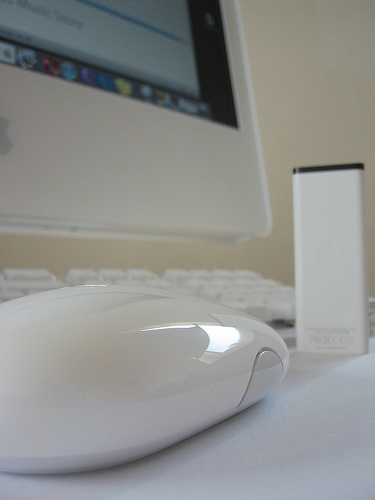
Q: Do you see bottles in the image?
A: No, there are no bottles.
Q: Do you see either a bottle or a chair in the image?
A: No, there are no bottles or chairs.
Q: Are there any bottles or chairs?
A: No, there are no bottles or chairs.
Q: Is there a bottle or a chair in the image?
A: No, there are no bottles or chairs.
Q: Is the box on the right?
A: Yes, the box is on the right of the image.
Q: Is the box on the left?
A: No, the box is on the right of the image.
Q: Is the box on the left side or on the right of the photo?
A: The box is on the right of the image.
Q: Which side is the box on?
A: The box is on the right of the image.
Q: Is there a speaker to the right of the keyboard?
A: No, there is a box to the right of the keyboard.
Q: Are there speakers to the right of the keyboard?
A: No, there is a box to the right of the keyboard.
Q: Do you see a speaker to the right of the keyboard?
A: No, there is a box to the right of the keyboard.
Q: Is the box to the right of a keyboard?
A: Yes, the box is to the right of a keyboard.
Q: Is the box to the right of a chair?
A: No, the box is to the right of a keyboard.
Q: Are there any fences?
A: No, there are no fences.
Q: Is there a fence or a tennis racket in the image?
A: No, there are no fences or rackets.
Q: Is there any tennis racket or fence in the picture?
A: No, there are no fences or rackets.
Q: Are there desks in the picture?
A: Yes, there is a desk.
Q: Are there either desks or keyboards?
A: Yes, there is a desk.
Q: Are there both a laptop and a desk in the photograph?
A: No, there is a desk but no laptops.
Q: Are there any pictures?
A: No, there are no pictures.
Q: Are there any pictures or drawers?
A: No, there are no pictures or drawers.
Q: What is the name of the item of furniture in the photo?
A: The piece of furniture is a desk.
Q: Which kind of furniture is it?
A: The piece of furniture is a desk.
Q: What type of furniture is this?
A: This is a desk.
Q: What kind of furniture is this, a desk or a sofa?
A: This is a desk.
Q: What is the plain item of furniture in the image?
A: The piece of furniture is a desk.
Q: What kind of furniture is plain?
A: The furniture is a desk.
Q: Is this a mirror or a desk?
A: This is a desk.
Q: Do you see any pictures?
A: No, there are no pictures.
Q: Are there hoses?
A: No, there are no hoses.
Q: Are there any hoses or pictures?
A: No, there are no hoses or pictures.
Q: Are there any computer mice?
A: Yes, there is a computer mouse.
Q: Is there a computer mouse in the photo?
A: Yes, there is a computer mouse.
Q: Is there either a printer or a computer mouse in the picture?
A: Yes, there is a computer mouse.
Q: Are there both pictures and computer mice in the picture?
A: No, there is a computer mouse but no pictures.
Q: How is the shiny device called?
A: The device is a computer mouse.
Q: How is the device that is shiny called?
A: The device is a computer mouse.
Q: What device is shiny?
A: The device is a computer mouse.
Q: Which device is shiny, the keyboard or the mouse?
A: The mouse is shiny.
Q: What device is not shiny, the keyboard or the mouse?
A: The keyboard is not shiny.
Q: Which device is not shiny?
A: The device is a keyboard.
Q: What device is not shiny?
A: The device is a keyboard.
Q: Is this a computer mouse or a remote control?
A: This is a computer mouse.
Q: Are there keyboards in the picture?
A: Yes, there is a keyboard.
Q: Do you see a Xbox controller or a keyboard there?
A: Yes, there is a keyboard.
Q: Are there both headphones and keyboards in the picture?
A: No, there is a keyboard but no headphones.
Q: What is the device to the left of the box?
A: The device is a keyboard.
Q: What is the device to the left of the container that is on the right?
A: The device is a keyboard.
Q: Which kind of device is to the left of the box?
A: The device is a keyboard.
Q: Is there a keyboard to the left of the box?
A: Yes, there is a keyboard to the left of the box.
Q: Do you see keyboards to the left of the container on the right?
A: Yes, there is a keyboard to the left of the box.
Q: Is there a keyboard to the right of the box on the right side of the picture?
A: No, the keyboard is to the left of the box.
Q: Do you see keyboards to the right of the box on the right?
A: No, the keyboard is to the left of the box.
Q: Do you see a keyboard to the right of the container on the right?
A: No, the keyboard is to the left of the box.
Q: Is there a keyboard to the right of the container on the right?
A: No, the keyboard is to the left of the box.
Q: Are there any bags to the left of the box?
A: No, there is a keyboard to the left of the box.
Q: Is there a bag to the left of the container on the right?
A: No, there is a keyboard to the left of the box.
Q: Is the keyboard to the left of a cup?
A: No, the keyboard is to the left of the box.